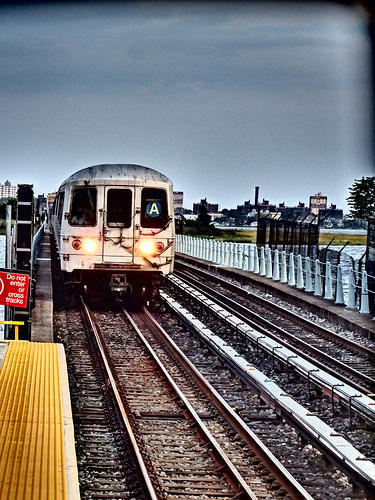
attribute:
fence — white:
[174, 232, 373, 317]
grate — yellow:
[0, 336, 71, 498]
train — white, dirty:
[46, 160, 179, 304]